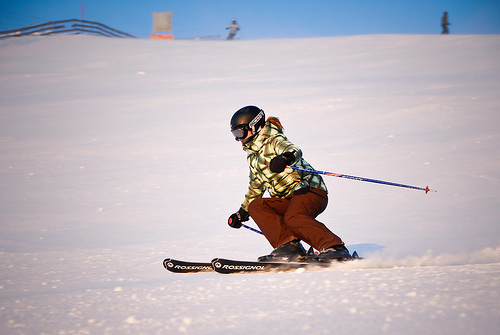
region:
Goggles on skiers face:
[227, 111, 264, 141]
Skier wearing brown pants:
[222, 100, 352, 264]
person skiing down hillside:
[155, 102, 438, 283]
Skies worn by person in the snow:
[163, 255, 375, 275]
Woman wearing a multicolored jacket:
[220, 103, 353, 257]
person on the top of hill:
[221, 16, 243, 38]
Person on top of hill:
[435, 7, 455, 37]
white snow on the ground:
[41, 174, 156, 216]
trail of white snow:
[396, 238, 458, 272]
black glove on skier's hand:
[256, 148, 298, 173]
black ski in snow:
[155, 248, 300, 275]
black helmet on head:
[223, 99, 268, 140]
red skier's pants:
[232, 181, 347, 256]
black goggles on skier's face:
[203, 98, 276, 149]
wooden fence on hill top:
[0, 18, 139, 40]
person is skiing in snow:
[161, 104, 437, 275]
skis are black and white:
[162, 248, 364, 273]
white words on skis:
[161, 258, 266, 275]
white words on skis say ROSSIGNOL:
[174, 258, 266, 274]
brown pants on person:
[248, 184, 348, 251]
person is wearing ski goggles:
[228, 125, 247, 140]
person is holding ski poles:
[221, 156, 438, 236]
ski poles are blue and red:
[228, 159, 438, 239]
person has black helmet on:
[228, 103, 265, 130]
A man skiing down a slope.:
[156, 95, 435, 278]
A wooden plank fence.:
[0, 18, 148, 43]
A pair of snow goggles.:
[230, 123, 250, 139]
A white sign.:
[148, 10, 175, 44]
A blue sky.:
[0, 0, 497, 34]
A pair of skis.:
[159, 250, 366, 279]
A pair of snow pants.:
[250, 184, 355, 251]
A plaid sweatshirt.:
[236, 119, 331, 214]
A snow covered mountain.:
[0, 35, 497, 331]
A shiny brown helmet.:
[230, 102, 267, 134]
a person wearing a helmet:
[228, 103, 268, 148]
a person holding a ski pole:
[268, 151, 444, 201]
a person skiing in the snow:
[165, 102, 340, 282]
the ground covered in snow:
[20, 35, 186, 185]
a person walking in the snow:
[437, 9, 459, 36]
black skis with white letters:
[155, 252, 356, 283]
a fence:
[7, 15, 137, 46]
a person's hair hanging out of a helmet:
[263, 113, 285, 132]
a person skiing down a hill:
[220, 16, 246, 41]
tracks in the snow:
[392, 245, 497, 320]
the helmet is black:
[216, 96, 268, 145]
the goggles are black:
[234, 130, 257, 142]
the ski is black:
[213, 251, 288, 272]